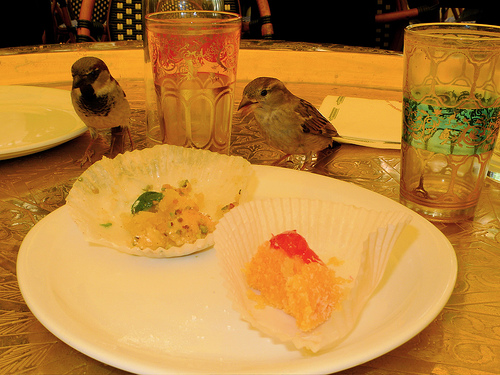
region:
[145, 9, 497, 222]
two glasses on table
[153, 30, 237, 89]
red design on glass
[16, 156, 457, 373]
round white plate on table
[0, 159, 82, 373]
gold design on table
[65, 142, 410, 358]
two papers on plate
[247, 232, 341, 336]
partially eaten food on paper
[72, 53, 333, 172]
two birds on table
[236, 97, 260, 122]
open beak on bird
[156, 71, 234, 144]
water inside of glass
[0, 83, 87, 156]
empty white plate on table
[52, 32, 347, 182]
two birds on the table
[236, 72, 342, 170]
an open beaked bird on the table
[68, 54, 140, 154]
a dark chested bird on the table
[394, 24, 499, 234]
a large drinking glass with green and gold accents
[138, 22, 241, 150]
a drinking glass with red and gold accents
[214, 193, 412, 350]
a dessert on a cupcake liner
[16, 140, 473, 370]
food on a white platter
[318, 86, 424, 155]
white napkin in the background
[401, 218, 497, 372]
a gold toned table top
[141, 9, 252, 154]
the glass is half filled with liquid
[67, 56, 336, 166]
two sparrows by a glass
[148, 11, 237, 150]
cup of water with the red design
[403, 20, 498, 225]
glass of water with the green design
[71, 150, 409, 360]
two pastries in white paper cups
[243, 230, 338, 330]
pastry with the red cherry on top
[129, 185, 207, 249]
pastry with the green cherry on top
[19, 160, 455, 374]
round white plate with deserts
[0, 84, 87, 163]
an empty white plate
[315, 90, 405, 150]
white napkin on the table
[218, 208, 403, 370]
Food on a white plate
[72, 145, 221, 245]
Food on a white plate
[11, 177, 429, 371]
White plate with food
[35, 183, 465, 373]
White plate sitting on the table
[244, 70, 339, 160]
Small bird sitting on the table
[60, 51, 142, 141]
Small bird sitting on the table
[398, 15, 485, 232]
Small glass sitting on the table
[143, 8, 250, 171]
Small glass sitting on the table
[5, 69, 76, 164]
White plate on table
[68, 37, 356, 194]
Small birds dining on the table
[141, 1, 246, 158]
a glass of water on the table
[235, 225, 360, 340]
a piece of cake on the table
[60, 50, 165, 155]
a bird on the table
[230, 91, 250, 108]
the beak of a bird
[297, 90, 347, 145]
the feather of a bird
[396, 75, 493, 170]
a glass with blue paintings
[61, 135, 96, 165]
the leg of a bird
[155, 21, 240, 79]
red paintings on a glass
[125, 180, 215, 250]
food on the plate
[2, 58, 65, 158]
another plate on the side